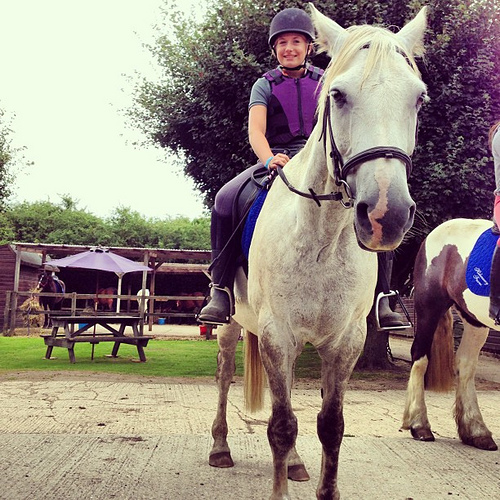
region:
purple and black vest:
[261, 66, 320, 147]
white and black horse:
[193, 13, 413, 498]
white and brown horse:
[402, 200, 499, 442]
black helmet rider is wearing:
[265, 6, 311, 67]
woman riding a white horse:
[187, 4, 345, 328]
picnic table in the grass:
[43, 312, 153, 368]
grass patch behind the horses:
[5, 333, 354, 373]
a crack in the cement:
[78, 390, 119, 416]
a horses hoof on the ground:
[194, 427, 256, 492]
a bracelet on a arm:
[252, 138, 299, 182]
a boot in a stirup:
[188, 271, 269, 338]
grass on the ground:
[160, 338, 201, 383]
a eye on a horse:
[317, 78, 362, 126]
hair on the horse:
[342, 20, 396, 84]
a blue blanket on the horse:
[460, 224, 488, 298]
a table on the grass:
[42, 300, 172, 367]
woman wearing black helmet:
[188, 5, 351, 325]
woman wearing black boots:
[183, 0, 345, 327]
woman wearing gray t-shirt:
[186, 3, 376, 321]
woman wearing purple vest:
[200, 7, 361, 320]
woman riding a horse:
[167, 15, 389, 471]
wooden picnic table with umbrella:
[38, 305, 153, 367]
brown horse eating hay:
[28, 266, 78, 332]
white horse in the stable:
[132, 280, 155, 329]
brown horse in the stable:
[89, 280, 121, 315]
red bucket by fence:
[194, 318, 214, 340]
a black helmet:
[267, 5, 319, 68]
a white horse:
[207, 2, 430, 499]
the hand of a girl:
[261, 153, 292, 170]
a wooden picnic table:
[35, 313, 155, 363]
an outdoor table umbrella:
[41, 243, 151, 280]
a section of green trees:
[104, 208, 214, 245]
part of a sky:
[0, 0, 89, 151]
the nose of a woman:
[280, 40, 297, 52]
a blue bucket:
[152, 314, 166, 327]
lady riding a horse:
[208, 0, 438, 349]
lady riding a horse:
[203, 6, 463, 326]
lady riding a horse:
[215, 12, 396, 294]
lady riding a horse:
[218, 0, 405, 277]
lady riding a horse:
[193, 2, 445, 331]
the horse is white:
[274, 8, 431, 399]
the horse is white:
[240, 5, 456, 354]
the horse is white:
[212, 0, 428, 317]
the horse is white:
[200, 8, 465, 394]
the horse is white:
[165, 8, 449, 392]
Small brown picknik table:
[37, 311, 158, 365]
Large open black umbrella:
[42, 231, 145, 304]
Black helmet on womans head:
[243, 4, 322, 75]